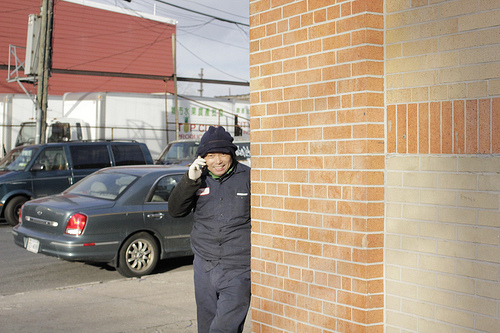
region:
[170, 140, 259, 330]
woman wearing a blue uniform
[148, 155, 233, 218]
woman has long sleeves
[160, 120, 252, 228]
the woman is holding a phone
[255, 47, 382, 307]
this is a brick wall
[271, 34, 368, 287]
bricks on wall or orange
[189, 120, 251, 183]
face of the person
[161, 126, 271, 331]
a woman standing on earth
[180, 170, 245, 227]
a woman wearing jacket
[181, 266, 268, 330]
a woman wearing pant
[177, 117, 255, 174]
a woman wearing hat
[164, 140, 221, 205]
a woman wearing gloves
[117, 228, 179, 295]
tire of the wall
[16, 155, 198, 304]
a car in the road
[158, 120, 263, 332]
person standing near the wall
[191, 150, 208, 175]
phone in the person's hand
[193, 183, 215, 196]
name tag on a shirt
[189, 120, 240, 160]
dark blue hat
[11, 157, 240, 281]
grey colored sedan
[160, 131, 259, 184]
portion of a grey van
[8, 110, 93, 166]
cab of a white truck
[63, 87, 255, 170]
cargo area of a white truck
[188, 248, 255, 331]
grey work pants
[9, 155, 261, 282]
grey passenger car on the street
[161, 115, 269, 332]
person on the phone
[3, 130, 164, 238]
dark green colored van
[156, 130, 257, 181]
grey van on the street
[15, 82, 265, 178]
white truck and cargo trailer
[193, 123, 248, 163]
person's dark colored hat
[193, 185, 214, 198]
name tag on a work shirt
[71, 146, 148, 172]
dark windows on a van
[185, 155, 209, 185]
white gloved hand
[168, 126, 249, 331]
A man talking on cell phone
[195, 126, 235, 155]
Black cap on the man's head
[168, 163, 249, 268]
Black jacket of the man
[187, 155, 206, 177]
White glove on the man's hand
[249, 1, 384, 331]
Brown brick pillar of a building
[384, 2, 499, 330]
Beige wall of the building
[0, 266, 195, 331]
Sidewalk of a road where the man is standing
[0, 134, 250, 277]
Vehicles on the road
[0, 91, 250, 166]
A white wall bordering the road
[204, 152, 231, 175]
Smiling face of the man